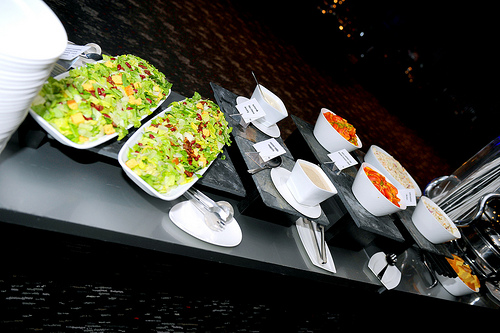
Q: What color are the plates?
A: White.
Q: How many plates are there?
A: Two.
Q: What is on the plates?
A: Salads.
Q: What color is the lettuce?
A: Green.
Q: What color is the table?
A: Silver.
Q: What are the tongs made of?
A: Metal.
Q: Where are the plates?
A: On the table.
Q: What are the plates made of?
A: Porcelain.